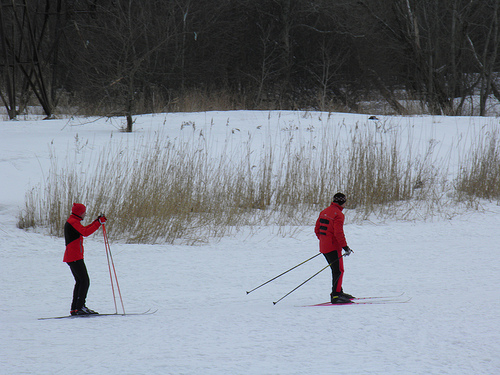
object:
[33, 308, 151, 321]
skis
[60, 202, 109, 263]
red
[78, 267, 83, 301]
black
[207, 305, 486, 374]
snow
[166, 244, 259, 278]
ground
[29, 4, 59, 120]
trees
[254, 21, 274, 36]
leaves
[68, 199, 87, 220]
hat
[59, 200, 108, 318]
person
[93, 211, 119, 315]
poles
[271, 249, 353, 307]
poles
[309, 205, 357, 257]
jacket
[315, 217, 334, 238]
stripes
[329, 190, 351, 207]
hat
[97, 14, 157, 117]
tree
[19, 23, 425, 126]
distance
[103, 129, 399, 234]
grass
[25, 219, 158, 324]
sport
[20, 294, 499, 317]
trail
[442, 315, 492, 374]
fresh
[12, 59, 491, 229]
wilderness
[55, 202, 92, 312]
suit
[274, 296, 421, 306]
skiis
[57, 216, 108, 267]
coat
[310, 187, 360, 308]
people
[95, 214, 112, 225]
hands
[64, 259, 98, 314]
pants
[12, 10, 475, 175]
background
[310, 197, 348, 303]
outfit